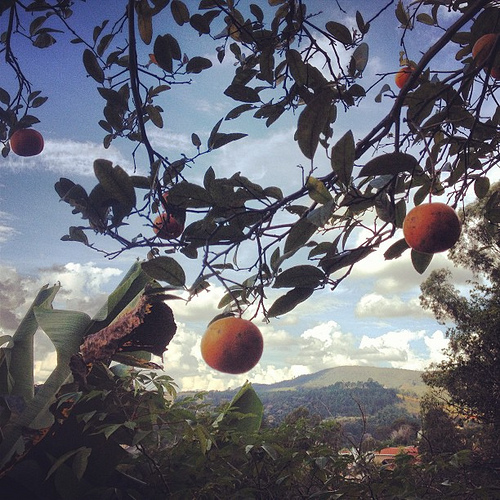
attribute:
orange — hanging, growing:
[395, 196, 462, 253]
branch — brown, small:
[408, 63, 477, 204]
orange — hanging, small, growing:
[391, 62, 422, 91]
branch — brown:
[396, 0, 425, 64]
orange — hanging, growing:
[191, 311, 270, 377]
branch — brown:
[201, 191, 273, 313]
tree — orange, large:
[2, 1, 500, 343]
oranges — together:
[145, 183, 192, 243]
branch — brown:
[115, 6, 180, 218]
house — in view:
[370, 441, 428, 473]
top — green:
[320, 360, 443, 376]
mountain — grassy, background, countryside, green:
[199, 359, 500, 446]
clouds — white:
[284, 21, 376, 103]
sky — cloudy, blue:
[2, 2, 499, 395]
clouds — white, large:
[2, 262, 500, 394]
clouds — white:
[340, 157, 500, 322]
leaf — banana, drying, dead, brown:
[80, 278, 189, 383]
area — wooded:
[179, 381, 422, 448]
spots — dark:
[237, 330, 247, 340]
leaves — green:
[322, 129, 358, 189]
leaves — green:
[92, 155, 143, 212]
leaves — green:
[292, 85, 339, 158]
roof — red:
[375, 441, 423, 457]